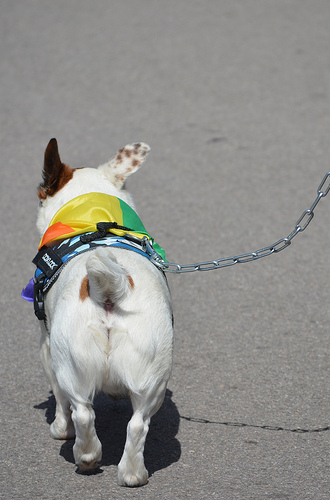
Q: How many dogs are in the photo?
A: One.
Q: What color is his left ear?
A: Brown.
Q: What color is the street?
A: Gray.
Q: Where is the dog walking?
A: Street.